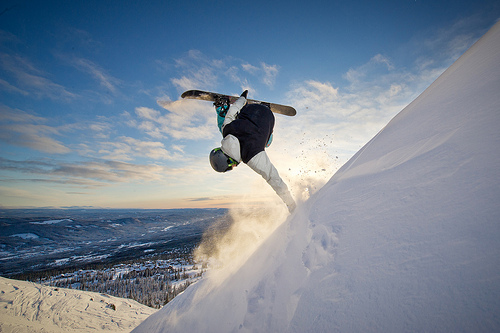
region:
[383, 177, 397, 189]
part of a hill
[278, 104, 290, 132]
part of a board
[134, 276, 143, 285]
part of a hill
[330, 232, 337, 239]
edge of a hill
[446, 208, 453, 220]
edge of a hill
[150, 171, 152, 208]
part of a cloud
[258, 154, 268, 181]
part of a board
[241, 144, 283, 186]
edge of a board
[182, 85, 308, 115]
this is a surf board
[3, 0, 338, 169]
this is the sky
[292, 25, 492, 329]
this is white snow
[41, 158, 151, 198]
these are clouds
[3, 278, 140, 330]
this is a hill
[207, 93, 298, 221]
this is a person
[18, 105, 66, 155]
this is a cloud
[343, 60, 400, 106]
this is a cloud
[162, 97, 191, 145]
this is a cloud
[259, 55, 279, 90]
this is a cloud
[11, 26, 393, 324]
this is on a mountain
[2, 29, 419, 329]
this is a nature setting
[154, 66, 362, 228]
this person is snowboarding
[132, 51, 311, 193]
this is a snowboarder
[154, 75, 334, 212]
the person is upside down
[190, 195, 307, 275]
the snow is splashed up here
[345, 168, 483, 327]
the mountainside is white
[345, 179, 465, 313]
the mountainside is covered in snow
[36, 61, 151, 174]
the sky is blue and white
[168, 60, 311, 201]
Girl on snowboard in air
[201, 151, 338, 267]
hand in snow sending snow in the air.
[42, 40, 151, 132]
clouds in the blue sky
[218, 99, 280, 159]
black and white snow jacket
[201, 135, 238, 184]
helmet and white hood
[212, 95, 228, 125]
blue snow pants and black shoes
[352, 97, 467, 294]
white snow and sky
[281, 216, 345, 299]
rough snow has been touched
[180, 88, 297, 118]
A grey snowboard on a snowboarder.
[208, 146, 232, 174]
Grey helmet on a snowboarder.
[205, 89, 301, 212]
A snowboarder upside down with a grey helmet on.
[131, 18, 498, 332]
Tall white slope a snowboarder is over.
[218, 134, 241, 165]
White hood on a person snowboarding.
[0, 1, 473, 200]
Blue sky with clouds.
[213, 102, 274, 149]
Turquoise pants on a snowboarder.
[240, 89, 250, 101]
Black glove on the right hand of a snowboarder.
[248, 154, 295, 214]
Extended left arm of a snowboarder.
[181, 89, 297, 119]
A long black and grey snowboard.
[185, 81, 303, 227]
snowboarder in the air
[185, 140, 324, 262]
powdery spray of snow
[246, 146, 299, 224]
arm of a person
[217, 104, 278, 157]
black hoodie vest on a man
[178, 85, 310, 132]
snowboard in the air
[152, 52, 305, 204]
man doing tricks on snowboard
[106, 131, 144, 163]
white clouds in blue sky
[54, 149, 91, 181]
white clouds in blue sky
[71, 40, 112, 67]
white clouds in blue sky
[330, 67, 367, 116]
white clouds in blue sky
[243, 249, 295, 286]
white snow on side of hill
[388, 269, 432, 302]
white snow on side of hill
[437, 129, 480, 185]
white snow on side of hill